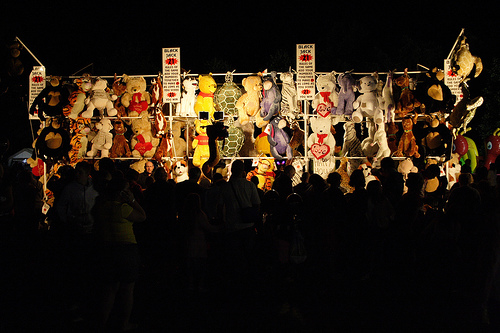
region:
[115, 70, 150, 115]
A teddy bear holding a heart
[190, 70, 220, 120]
A 'Winnie the Pooh' doll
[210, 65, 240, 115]
A green turtle doll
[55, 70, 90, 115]
A 'Tigger' doll hanging on a rack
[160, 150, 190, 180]
A brown/white dog doll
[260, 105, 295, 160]
An 'Eor' doll hanging on a rack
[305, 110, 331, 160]
A white teddy bear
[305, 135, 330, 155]
A heart that says 'Love'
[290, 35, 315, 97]
A white/orange sign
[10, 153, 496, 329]
A crowd of people looking at stuffed animals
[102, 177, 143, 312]
woman wearing yellow shirt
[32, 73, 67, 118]
monkey shaped stuffed animal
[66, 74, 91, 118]
tiger stuffed animal hanging up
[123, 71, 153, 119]
teddy bear stuffed animal hanging up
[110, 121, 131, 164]
scooby doo stuffed animal hanging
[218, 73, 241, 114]
turtle stuffed animal hanging up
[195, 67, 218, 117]
winnie the pooh stuffed animal hanging up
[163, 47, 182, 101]
white sign hanging with stuffed animals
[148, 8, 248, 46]
dark night time sky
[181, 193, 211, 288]
little girl looking at stuffed animals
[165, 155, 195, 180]
A white/brown/black dog doll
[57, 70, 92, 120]
A red/black 'Tigger' doll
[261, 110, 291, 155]
A purple 'Eor' doll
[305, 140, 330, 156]
A heart that reads 'Love'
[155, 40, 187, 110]
A orange/white sign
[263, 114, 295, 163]
a purple push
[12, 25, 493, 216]
plushies hanging from a display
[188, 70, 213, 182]
two Winnie the Pooh plushies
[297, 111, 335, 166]
a white teddy bear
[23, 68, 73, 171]
two brown monkeys on edge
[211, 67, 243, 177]
two green turtles plushies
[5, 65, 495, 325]
people in front plushies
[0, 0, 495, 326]
the scene is night outdoor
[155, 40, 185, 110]
a sign in front of plushies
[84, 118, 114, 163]
a brown plush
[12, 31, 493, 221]
Stuffed animals hanging on racks.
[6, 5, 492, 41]
The surrounding is very dark.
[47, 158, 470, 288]
People are looking at the hanging stuffed animals.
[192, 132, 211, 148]
The yellow bear wears a red t-shirt.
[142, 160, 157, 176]
A man is looking at the other people.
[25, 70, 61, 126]
The stuffed monkey has light brown chest.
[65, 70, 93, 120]
The stuffed tiger is standing next to the bear.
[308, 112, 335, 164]
The white stuffed bear wears a red bow tie.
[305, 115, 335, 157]
The white bear is holding a red heart shaped cushion.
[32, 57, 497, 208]
The stuffed animals are illuminated by a strong light.